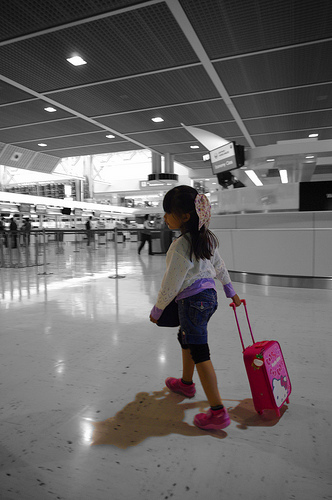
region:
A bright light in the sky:
[65, 55, 86, 66]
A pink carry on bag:
[228, 298, 292, 420]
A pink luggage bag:
[227, 299, 291, 418]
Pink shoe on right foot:
[164, 376, 195, 398]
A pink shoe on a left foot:
[193, 406, 229, 432]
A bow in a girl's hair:
[194, 191, 210, 232]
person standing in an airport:
[9, 216, 18, 247]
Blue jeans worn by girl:
[176, 289, 219, 342]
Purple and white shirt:
[148, 235, 235, 322]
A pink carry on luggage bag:
[229, 298, 291, 421]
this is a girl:
[85, 181, 260, 444]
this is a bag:
[224, 294, 304, 423]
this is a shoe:
[185, 400, 237, 442]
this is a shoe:
[156, 362, 204, 415]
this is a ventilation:
[62, 48, 94, 75]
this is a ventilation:
[149, 111, 174, 135]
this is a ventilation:
[100, 131, 128, 145]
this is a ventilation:
[306, 127, 328, 153]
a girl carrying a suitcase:
[151, 182, 291, 430]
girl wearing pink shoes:
[166, 374, 229, 428]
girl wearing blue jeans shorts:
[176, 288, 217, 343]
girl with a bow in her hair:
[195, 192, 211, 231]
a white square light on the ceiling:
[152, 117, 163, 123]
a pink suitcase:
[230, 298, 292, 417]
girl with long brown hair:
[162, 185, 218, 259]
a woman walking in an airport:
[137, 213, 155, 255]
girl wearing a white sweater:
[151, 230, 231, 307]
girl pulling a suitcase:
[120, 183, 307, 430]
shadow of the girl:
[93, 406, 177, 452]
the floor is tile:
[104, 455, 189, 487]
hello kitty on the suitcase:
[266, 370, 285, 414]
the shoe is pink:
[193, 404, 229, 430]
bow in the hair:
[187, 192, 217, 229]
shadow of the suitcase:
[235, 395, 256, 426]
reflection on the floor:
[51, 263, 87, 300]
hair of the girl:
[177, 231, 213, 260]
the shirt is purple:
[191, 283, 202, 293]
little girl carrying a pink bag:
[150, 185, 292, 430]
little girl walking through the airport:
[147, 184, 290, 430]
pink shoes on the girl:
[166, 376, 230, 433]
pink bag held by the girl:
[229, 298, 291, 419]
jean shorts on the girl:
[177, 288, 218, 363]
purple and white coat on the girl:
[149, 229, 236, 318]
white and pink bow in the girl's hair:
[193, 194, 211, 230]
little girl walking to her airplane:
[148, 186, 292, 431]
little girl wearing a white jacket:
[150, 181, 294, 428]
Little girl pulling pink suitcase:
[145, 175, 294, 454]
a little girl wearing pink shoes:
[146, 178, 246, 441]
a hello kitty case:
[225, 292, 294, 430]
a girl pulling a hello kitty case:
[147, 181, 292, 437]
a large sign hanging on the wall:
[205, 139, 247, 175]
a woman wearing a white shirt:
[133, 211, 160, 259]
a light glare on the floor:
[4, 257, 150, 321]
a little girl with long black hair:
[147, 182, 247, 442]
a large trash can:
[142, 225, 169, 260]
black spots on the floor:
[5, 367, 200, 493]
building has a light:
[66, 54, 87, 65]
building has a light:
[43, 106, 54, 112]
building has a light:
[37, 142, 45, 149]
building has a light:
[105, 132, 117, 139]